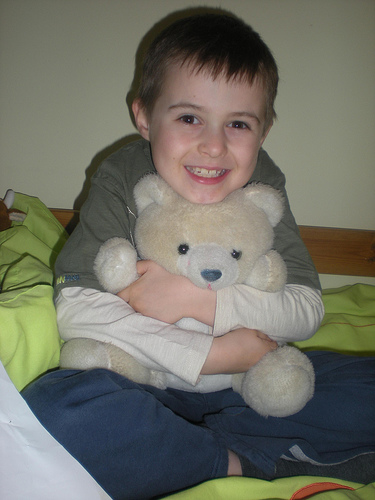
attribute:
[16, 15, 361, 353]
child — smiling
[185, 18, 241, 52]
hair — blonde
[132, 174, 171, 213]
ear — white bear's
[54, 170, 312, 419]
bear — teddy, white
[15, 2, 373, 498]
male — young, caucasian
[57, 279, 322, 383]
sleeves — white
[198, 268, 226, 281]
nose — bear's, black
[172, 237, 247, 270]
bear — white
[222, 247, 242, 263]
eye — teddy bear's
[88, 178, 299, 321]
bear — white, teddy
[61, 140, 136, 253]
shirt — grey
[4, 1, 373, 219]
wall — white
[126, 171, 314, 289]
bear — white, teddy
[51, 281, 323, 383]
shirt — white, long-sleeve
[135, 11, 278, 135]
hair — brown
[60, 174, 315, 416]
teddy bear — white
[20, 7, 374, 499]
boy — little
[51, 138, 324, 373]
arms — little, boy's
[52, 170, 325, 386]
boy`s arm — little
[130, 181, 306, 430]
bear — white, teddy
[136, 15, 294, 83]
hair — boy's, brown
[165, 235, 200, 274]
eyes — black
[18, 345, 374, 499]
sweatpants — for warmth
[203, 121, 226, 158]
nose — little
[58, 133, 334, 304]
shirt — gray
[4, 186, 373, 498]
sheet — green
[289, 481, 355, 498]
edge — orange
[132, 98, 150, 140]
ear — boy's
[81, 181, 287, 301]
teddy bear — white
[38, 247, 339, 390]
arm — boy's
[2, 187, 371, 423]
blanket — lime, green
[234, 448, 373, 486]
sock — gray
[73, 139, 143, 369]
tee shirt — gray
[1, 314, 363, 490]
cover — blue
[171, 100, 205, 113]
eyebrow — boy's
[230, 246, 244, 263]
eye — bear's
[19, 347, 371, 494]
pants — blue